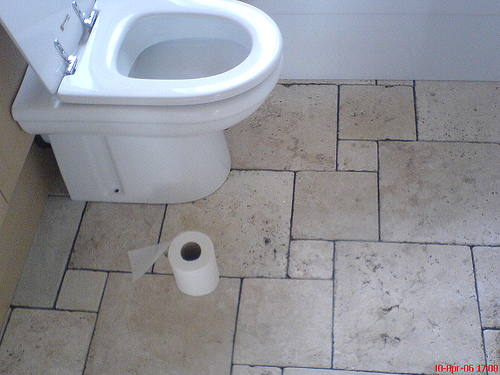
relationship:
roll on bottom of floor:
[126, 230, 220, 297] [0, 74, 460, 371]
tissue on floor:
[126, 231, 220, 297] [66, 188, 460, 337]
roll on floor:
[126, 230, 220, 297] [276, 123, 473, 325]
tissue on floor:
[126, 231, 220, 297] [0, 74, 460, 371]